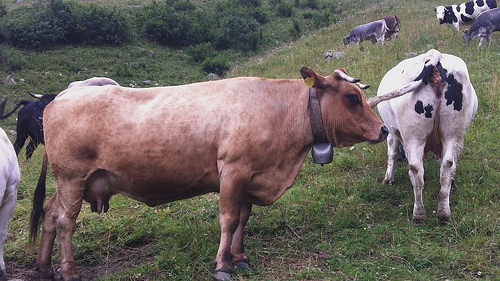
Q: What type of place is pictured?
A: It is a field.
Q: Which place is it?
A: It is a field.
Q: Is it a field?
A: Yes, it is a field.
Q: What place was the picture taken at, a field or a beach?
A: It was taken at a field.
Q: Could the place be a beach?
A: No, it is a field.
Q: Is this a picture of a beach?
A: No, the picture is showing a field.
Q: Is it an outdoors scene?
A: Yes, it is outdoors.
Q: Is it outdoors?
A: Yes, it is outdoors.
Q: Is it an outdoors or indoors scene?
A: It is outdoors.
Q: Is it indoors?
A: No, it is outdoors.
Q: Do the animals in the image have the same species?
A: Yes, all the animals are cows.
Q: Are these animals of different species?
A: No, all the animals are cows.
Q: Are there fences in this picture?
A: No, there are no fences.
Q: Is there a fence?
A: No, there are no fences.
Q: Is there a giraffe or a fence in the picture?
A: No, there are no fences or giraffes.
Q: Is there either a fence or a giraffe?
A: No, there are no fences or giraffes.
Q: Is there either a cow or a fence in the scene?
A: Yes, there is a cow.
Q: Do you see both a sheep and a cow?
A: No, there is a cow but no sheep.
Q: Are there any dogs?
A: No, there are no dogs.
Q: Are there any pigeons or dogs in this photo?
A: No, there are no dogs or pigeons.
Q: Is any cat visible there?
A: No, there are no cats.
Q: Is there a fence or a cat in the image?
A: No, there are no cats or fences.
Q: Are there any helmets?
A: No, there are no helmets.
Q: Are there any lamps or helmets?
A: No, there are no helmets or lamps.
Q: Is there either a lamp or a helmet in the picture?
A: No, there are no helmets or lamps.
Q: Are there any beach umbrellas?
A: No, there are no beach umbrellas.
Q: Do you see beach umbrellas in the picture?
A: No, there are no beach umbrellas.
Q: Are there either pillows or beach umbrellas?
A: No, there are no beach umbrellas or pillows.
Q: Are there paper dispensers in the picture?
A: No, there are no paper dispensers.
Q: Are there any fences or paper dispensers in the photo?
A: No, there are no paper dispensers or fences.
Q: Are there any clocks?
A: No, there are no clocks.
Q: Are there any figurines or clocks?
A: No, there are no clocks or figurines.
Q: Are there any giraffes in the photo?
A: No, there are no giraffes.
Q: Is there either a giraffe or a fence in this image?
A: No, there are no giraffes or fences.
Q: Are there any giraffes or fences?
A: No, there are no giraffes or fences.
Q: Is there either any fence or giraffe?
A: No, there are no giraffes or fences.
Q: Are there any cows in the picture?
A: Yes, there is a cow.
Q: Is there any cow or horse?
A: Yes, there is a cow.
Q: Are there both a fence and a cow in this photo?
A: No, there is a cow but no fences.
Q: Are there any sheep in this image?
A: No, there are no sheep.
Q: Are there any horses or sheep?
A: No, there are no sheep or horses.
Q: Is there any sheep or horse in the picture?
A: No, there are no sheep or horses.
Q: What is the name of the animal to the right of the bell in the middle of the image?
A: The animal is a cow.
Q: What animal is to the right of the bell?
A: The animal is a cow.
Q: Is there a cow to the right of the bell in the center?
A: Yes, there is a cow to the right of the bell.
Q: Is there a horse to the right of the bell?
A: No, there is a cow to the right of the bell.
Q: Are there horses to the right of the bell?
A: No, there is a cow to the right of the bell.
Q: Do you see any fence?
A: No, there are no fences.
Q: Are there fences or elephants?
A: No, there are no fences or elephants.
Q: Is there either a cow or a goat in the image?
A: Yes, there is a cow.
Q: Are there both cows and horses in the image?
A: No, there is a cow but no horses.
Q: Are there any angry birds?
A: No, there are no angry birds.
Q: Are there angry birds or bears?
A: No, there are no angry birds or bears.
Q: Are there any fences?
A: No, there are no fences.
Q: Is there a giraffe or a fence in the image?
A: No, there are no fences or giraffes.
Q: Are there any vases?
A: No, there are no vases.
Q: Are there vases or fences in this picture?
A: No, there are no vases or fences.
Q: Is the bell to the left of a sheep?
A: No, the bell is to the left of the cow.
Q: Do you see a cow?
A: Yes, there is a cow.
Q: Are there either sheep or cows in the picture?
A: Yes, there is a cow.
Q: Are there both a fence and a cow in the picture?
A: No, there is a cow but no fences.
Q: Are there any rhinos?
A: No, there are no rhinos.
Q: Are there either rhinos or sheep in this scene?
A: No, there are no rhinos or sheep.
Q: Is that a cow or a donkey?
A: That is a cow.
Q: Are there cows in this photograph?
A: Yes, there is a cow.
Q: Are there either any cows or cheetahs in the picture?
A: Yes, there is a cow.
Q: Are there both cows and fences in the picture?
A: No, there is a cow but no fences.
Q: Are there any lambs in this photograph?
A: No, there are no lambs.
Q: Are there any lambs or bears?
A: No, there are no lambs or bears.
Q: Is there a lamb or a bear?
A: No, there are no lambs or bears.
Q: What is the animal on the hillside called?
A: The animal is a cow.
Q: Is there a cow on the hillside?
A: Yes, there is a cow on the hillside.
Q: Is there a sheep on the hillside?
A: No, there is a cow on the hillside.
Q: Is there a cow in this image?
A: Yes, there is a cow.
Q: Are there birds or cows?
A: Yes, there is a cow.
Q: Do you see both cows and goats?
A: No, there is a cow but no goats.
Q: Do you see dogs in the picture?
A: No, there are no dogs.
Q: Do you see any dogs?
A: No, there are no dogs.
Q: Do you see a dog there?
A: No, there are no dogs.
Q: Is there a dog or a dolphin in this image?
A: No, there are no dogs or dolphins.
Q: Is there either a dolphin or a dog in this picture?
A: No, there are no dogs or dolphins.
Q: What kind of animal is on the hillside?
A: The animal is a cow.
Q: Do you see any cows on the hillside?
A: Yes, there is a cow on the hillside.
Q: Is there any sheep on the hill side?
A: No, there is a cow on the hill side.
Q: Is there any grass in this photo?
A: Yes, there is grass.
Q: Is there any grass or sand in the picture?
A: Yes, there is grass.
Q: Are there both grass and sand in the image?
A: No, there is grass but no sand.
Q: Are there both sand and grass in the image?
A: No, there is grass but no sand.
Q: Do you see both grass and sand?
A: No, there is grass but no sand.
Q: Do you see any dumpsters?
A: No, there are no dumpsters.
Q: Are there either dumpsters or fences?
A: No, there are no dumpsters or fences.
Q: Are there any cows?
A: Yes, there is a cow.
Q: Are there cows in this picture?
A: Yes, there is a cow.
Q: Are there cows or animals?
A: Yes, there is a cow.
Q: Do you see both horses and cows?
A: No, there is a cow but no horses.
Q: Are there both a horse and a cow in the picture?
A: No, there is a cow but no horses.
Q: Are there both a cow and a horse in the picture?
A: No, there is a cow but no horses.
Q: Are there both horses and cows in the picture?
A: No, there is a cow but no horses.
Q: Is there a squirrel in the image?
A: No, there are no squirrels.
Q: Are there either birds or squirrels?
A: No, there are no squirrels or birds.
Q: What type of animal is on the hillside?
A: The animal is a cow.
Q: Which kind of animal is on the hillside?
A: The animal is a cow.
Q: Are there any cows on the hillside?
A: Yes, there is a cow on the hillside.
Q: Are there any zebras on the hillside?
A: No, there is a cow on the hillside.